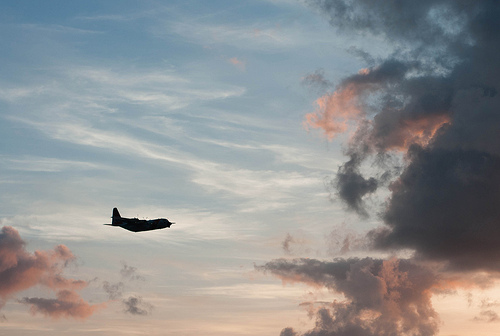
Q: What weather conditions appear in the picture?
A: It is clear.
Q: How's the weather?
A: It is clear.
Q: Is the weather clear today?
A: Yes, it is clear.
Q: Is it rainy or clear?
A: It is clear.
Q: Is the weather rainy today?
A: No, it is clear.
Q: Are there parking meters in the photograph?
A: No, there are no parking meters.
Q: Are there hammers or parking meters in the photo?
A: No, there are no parking meters or hammers.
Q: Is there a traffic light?
A: No, there are no traffic lights.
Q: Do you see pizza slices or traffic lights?
A: No, there are no traffic lights or pizza slices.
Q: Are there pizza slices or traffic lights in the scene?
A: No, there are no traffic lights or pizza slices.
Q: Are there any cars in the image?
A: No, there are no cars.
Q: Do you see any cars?
A: No, there are no cars.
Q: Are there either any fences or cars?
A: No, there are no cars or fences.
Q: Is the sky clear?
A: Yes, the sky is clear.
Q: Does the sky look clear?
A: Yes, the sky is clear.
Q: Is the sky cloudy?
A: No, the sky is clear.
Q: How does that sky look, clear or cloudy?
A: The sky is clear.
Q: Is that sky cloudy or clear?
A: The sky is clear.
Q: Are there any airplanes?
A: Yes, there is an airplane.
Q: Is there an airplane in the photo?
A: Yes, there is an airplane.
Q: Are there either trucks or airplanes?
A: Yes, there is an airplane.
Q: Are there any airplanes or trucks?
A: Yes, there is an airplane.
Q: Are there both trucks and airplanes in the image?
A: No, there is an airplane but no trucks.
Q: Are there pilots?
A: No, there are no pilots.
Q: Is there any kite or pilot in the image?
A: No, there are no pilots or kites.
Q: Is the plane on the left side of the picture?
A: Yes, the plane is on the left of the image.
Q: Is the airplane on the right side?
A: No, the airplane is on the left of the image.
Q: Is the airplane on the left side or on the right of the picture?
A: The airplane is on the left of the image.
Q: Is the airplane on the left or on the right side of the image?
A: The airplane is on the left of the image.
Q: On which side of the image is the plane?
A: The plane is on the left of the image.